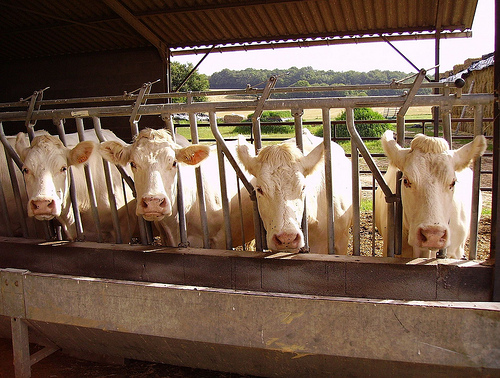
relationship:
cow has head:
[112, 120, 261, 238] [106, 129, 206, 223]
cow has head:
[29, 125, 130, 236] [12, 128, 90, 225]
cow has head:
[235, 134, 367, 261] [241, 132, 330, 255]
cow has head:
[368, 122, 480, 275] [383, 126, 487, 255]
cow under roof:
[112, 120, 261, 238] [3, 1, 477, 59]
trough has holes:
[2, 213, 492, 374] [1, 104, 491, 260]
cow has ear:
[112, 120, 261, 238] [172, 144, 214, 168]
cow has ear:
[112, 120, 261, 238] [94, 140, 138, 168]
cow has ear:
[29, 125, 130, 236] [66, 140, 98, 166]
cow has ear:
[235, 134, 367, 261] [292, 143, 332, 173]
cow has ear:
[235, 134, 367, 261] [233, 135, 263, 177]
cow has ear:
[368, 122, 480, 275] [379, 126, 414, 170]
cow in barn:
[29, 125, 130, 236] [4, 2, 479, 242]